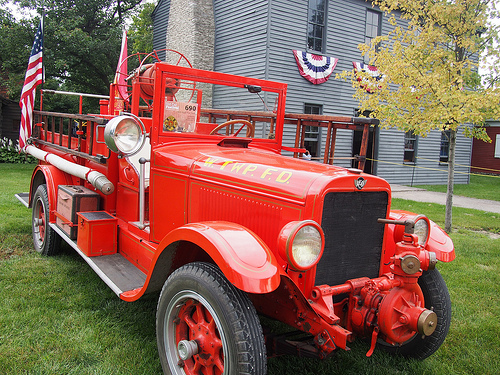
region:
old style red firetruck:
[22, 5, 455, 371]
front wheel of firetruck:
[147, 248, 267, 370]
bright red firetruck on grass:
[16, 20, 491, 372]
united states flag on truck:
[5, 0, 64, 162]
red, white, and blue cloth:
[349, 54, 391, 104]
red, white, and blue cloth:
[291, 45, 339, 93]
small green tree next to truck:
[351, 5, 498, 227]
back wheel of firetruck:
[19, 177, 64, 254]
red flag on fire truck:
[97, 23, 147, 112]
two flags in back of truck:
[0, 5, 142, 160]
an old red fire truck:
[13, 45, 458, 373]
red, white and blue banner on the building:
[288, 46, 339, 83]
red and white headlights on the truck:
[276, 213, 434, 271]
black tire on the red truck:
[152, 258, 270, 374]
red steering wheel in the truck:
[208, 115, 255, 142]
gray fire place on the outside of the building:
[163, 0, 217, 127]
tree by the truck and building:
[333, 0, 498, 235]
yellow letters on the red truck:
[198, 152, 298, 189]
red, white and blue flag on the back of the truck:
[13, 10, 46, 150]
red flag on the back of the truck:
[112, 24, 130, 106]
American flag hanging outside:
[15, 6, 42, 148]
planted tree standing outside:
[386, 5, 496, 205]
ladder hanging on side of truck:
[35, 110, 105, 165]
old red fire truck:
[31, 51, 448, 358]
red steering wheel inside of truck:
[216, 120, 258, 138]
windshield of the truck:
[166, 78, 282, 136]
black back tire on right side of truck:
[23, 187, 56, 252]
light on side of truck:
[105, 112, 145, 165]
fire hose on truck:
[119, 57, 173, 104]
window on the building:
[302, 3, 326, 50]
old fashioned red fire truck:
[13, 47, 453, 374]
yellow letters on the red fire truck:
[201, 153, 291, 183]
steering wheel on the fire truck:
[208, 118, 255, 136]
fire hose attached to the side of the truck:
[26, 141, 113, 194]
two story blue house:
[149, 1, 489, 165]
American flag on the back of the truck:
[16, 15, 45, 155]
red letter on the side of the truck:
[197, 107, 382, 172]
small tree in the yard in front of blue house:
[336, 0, 498, 233]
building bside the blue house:
[471, 116, 499, 174]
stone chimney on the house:
[161, 0, 217, 120]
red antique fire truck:
[17, 40, 468, 373]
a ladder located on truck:
[27, 103, 107, 161]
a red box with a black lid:
[74, 206, 116, 257]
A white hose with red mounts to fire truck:
[20, 140, 114, 195]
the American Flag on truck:
[10, 15, 60, 157]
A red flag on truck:
[115, 27, 128, 104]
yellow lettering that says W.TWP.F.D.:
[200, 153, 293, 196]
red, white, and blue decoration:
[286, 48, 341, 84]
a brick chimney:
[165, 0, 215, 115]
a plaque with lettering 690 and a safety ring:
[160, 98, 205, 136]